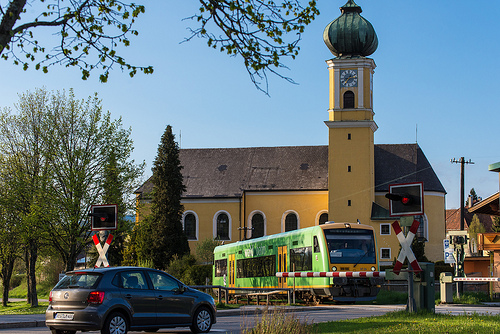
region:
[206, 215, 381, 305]
Green and yellow passenger rail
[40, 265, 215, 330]
Gray hatchback car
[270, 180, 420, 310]
Lowered railroad gate arm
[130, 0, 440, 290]
Yellow building with clock tower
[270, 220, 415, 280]
Red and white striped gate arm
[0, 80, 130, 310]
Green trees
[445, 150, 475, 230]
Electrical power pole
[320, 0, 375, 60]
Green dome over clock tower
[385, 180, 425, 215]
Red stop light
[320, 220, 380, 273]
Front window of passenger rail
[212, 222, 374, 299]
Green train coming from afar.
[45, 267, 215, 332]
Gray car waiting for the green light.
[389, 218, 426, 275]
Stop sign in front of the car.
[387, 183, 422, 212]
Red light on the left of the car.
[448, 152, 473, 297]
Electric pole near the building.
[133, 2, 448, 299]
Big yellow building that looks like a church.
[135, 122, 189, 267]
Pine tree in front of building.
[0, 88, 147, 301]
Several trees containing lots of leaves.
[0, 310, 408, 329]
Alley that leads on the other side of the street.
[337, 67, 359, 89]
Clock on top of the building.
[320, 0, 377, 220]
the clock tower has an onion shaped dome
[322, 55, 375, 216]
the clock tower is yellow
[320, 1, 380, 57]
the onion shaped dome is green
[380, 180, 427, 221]
a traffic signal light is red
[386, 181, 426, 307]
a train crossing signal is under the traffic signal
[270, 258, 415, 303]
the gate is down for a passing train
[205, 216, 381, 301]
the train is green and yellow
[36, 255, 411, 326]
a car is stopped at the gate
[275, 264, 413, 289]
the gate is red and white stripes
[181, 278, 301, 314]
a wooden fence along the road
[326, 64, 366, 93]
Black and white clock face.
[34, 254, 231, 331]
Car on a road.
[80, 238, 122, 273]
Rail road crossing sign.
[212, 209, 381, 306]
Yellow rail way train.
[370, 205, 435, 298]
Black and white railroad sign.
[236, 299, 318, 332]
Tall patch of grass.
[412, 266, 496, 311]
Railroad blocking arm that is down.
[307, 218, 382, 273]
Front window of a train.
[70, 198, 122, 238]
Light for a rail road stop.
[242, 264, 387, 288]
Black and white rail way guard.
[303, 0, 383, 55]
a large finial on a church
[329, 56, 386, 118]
a clock tower on a church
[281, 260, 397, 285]
a bollard in front of a car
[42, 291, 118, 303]
red tail lights on the back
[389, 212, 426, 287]
a red and white traffic crossing sign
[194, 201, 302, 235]
windows in a church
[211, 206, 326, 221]
arches at the top of the windows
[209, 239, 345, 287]
a green and yellow train crossing the tracks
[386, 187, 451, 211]
a traffic light signalling on red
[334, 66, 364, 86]
a large clock over the church